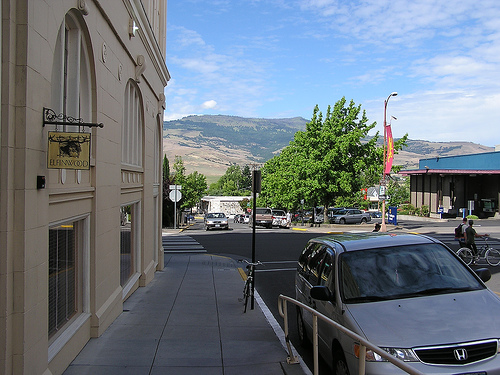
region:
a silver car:
[292, 227, 498, 372]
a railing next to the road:
[268, 291, 432, 374]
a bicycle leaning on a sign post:
[236, 254, 261, 317]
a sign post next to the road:
[248, 165, 265, 308]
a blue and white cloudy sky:
[168, 0, 496, 151]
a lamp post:
[378, 87, 400, 232]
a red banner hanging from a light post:
[378, 118, 398, 183]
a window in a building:
[45, 209, 94, 351]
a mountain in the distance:
[162, 114, 498, 174]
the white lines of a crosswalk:
[241, 256, 304, 274]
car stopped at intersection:
[200, 214, 237, 232]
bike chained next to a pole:
[239, 249, 261, 311]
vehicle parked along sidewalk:
[283, 220, 496, 373]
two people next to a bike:
[448, 214, 499, 264]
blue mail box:
[382, 204, 404, 224]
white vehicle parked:
[273, 203, 289, 228]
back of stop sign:
[167, 184, 187, 204]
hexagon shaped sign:
[168, 185, 187, 202]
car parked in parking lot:
[329, 206, 372, 226]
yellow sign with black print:
[40, 126, 97, 171]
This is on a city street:
[7, 20, 452, 348]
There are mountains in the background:
[178, 105, 293, 175]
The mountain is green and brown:
[172, 108, 292, 177]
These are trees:
[261, 100, 428, 222]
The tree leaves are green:
[244, 90, 495, 270]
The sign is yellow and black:
[27, 98, 156, 233]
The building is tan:
[25, 17, 264, 360]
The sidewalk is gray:
[138, 274, 258, 371]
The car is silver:
[298, 223, 481, 333]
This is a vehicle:
[298, 229, 498, 359]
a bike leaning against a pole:
[231, 255, 268, 315]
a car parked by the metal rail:
[295, 228, 495, 373]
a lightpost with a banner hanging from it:
[381, 87, 399, 231]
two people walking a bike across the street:
[450, 215, 499, 265]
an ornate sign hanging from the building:
[40, 103, 107, 175]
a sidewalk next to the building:
[65, 252, 310, 372]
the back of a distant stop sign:
[166, 179, 183, 233]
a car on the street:
[201, 209, 232, 234]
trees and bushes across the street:
[165, 94, 426, 217]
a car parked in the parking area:
[295, 215, 491, 374]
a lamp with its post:
[380, 85, 401, 233]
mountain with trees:
[198, 112, 403, 215]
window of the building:
[43, 207, 96, 364]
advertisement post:
[243, 160, 262, 315]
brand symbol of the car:
[451, 344, 468, 366]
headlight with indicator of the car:
[336, 335, 419, 362]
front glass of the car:
[341, 247, 475, 303]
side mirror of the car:
[306, 281, 328, 301]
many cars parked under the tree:
[247, 199, 390, 231]